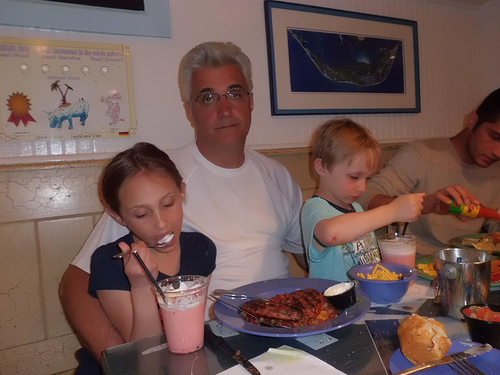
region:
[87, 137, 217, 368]
this is a person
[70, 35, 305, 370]
these are two people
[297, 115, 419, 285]
this is a person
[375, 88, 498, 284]
this is a person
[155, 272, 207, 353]
this is a glass with bevearage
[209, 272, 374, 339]
this is a plate of food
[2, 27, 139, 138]
this is a picture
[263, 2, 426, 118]
this is a picture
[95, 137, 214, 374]
the girl is feeding herself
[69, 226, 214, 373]
a navy shirt on a girl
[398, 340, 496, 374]
a knife on a plate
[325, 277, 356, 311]
white sauce in a small black bowl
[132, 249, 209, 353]
a pink drink with a straw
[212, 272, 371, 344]
a round blue plate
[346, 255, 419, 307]
a blue bowl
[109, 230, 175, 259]
a spoon in a girl's mouth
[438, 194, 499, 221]
a hot sauce bottle in a man's hand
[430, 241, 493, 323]
a small metal bucket on a table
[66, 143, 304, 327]
a white shirt on a man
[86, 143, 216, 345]
little girl sitting next to man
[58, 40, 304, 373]
man wearing prescription glasses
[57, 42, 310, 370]
man sitting between kids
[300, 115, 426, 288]
child sitting next to man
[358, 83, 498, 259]
man pouring hot sauce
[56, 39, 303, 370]
man wearing white t-shirt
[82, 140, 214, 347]
little girl eating a milk shake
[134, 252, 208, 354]
plastic cup with black straw in it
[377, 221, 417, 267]
plastic cup with black straw in it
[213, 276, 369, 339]
round plate in front of man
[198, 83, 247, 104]
glasses on the man's face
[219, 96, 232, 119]
nose on the man's face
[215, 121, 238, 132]
lips on the man's face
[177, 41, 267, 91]
the man's gray hair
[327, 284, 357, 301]
butter in black container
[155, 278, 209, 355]
glass with strawberry shake inside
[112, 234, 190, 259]
spoon in the girl's hand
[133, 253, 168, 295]
black straw in glass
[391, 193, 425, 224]
the little boy's right hand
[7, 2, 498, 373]
people sitting in restaurant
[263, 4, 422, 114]
photo in rectangle frame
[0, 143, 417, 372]
back of tan bench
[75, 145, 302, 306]
short sleeved tee shirt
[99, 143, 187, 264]
girl eating from spoon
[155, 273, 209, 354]
cup with pink liquid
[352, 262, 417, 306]
macaroni in blue bowl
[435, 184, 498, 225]
hand on tilted bottle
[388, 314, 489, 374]
bread and knife on plate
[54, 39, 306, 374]
man is holding girl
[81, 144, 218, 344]
girl is holding a spoon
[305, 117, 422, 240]
boy is holding a straw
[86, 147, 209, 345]
girl is wearing black shirt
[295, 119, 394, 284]
boy is wearing a blue shirt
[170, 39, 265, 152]
man is wearing glasses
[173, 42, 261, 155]
man has grey hair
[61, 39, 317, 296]
man is wearing a white shirt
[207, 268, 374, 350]
plate is blue color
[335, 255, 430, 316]
bowl is blue color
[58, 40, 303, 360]
gray-haired man in a white t-shirt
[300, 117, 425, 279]
a young boy in a light blue t-shirt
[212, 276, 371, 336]
blue plate with food in front of the man